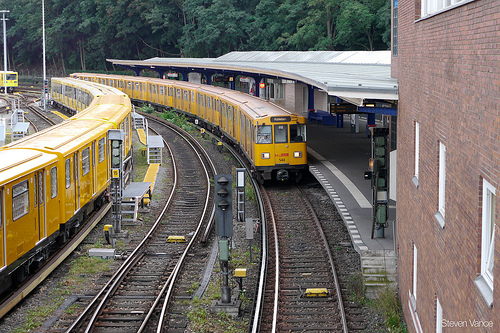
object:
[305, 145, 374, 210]
lines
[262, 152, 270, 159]
lights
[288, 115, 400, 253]
platform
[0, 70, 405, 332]
train yard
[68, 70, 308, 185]
train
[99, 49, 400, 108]
roof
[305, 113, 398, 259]
waiting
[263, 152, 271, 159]
lights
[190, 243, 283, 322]
sign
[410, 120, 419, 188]
windows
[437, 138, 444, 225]
windows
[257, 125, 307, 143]
windows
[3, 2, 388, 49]
trees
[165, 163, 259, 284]
sign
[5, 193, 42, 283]
sign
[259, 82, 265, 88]
lights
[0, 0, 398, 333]
train station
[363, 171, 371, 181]
sign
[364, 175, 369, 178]
arrow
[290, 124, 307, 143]
windshield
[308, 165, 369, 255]
white markings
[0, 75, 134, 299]
train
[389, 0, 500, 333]
wall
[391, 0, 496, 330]
building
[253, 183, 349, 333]
track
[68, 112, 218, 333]
track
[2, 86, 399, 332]
ground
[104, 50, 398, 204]
waiting area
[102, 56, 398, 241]
station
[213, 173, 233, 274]
arrow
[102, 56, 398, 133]
bad sentence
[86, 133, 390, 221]
no detoursign